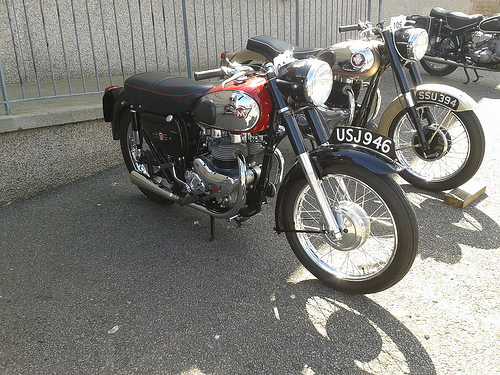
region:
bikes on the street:
[76, 22, 455, 272]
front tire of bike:
[270, 164, 405, 303]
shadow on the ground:
[247, 286, 353, 351]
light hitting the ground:
[418, 270, 477, 335]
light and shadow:
[347, 284, 452, 361]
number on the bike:
[321, 121, 395, 170]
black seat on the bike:
[139, 51, 195, 121]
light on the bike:
[291, 60, 342, 99]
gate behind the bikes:
[14, 16, 146, 77]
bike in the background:
[413, 7, 492, 64]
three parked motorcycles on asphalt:
[90, 10, 485, 308]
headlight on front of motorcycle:
[297, 57, 337, 109]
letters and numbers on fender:
[412, 86, 463, 109]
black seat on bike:
[120, 66, 206, 116]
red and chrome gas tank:
[202, 74, 272, 133]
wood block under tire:
[440, 179, 488, 214]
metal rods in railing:
[25, 19, 103, 88]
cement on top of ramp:
[24, 77, 104, 130]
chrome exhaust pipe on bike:
[122, 165, 190, 214]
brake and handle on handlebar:
[190, 62, 250, 92]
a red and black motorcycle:
[96, 23, 422, 305]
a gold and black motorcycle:
[237, 22, 488, 160]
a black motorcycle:
[397, 5, 498, 79]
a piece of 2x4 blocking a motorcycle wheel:
[436, 175, 488, 215]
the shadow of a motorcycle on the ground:
[199, 287, 442, 373]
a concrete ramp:
[3, 76, 162, 177]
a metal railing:
[1, 0, 383, 103]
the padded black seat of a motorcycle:
[122, 62, 212, 119]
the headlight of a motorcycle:
[302, 58, 341, 110]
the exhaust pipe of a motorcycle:
[123, 166, 183, 204]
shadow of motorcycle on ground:
[174, 250, 432, 374]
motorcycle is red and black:
[96, 25, 319, 206]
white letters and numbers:
[333, 116, 405, 160]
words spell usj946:
[319, 118, 394, 163]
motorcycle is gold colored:
[240, 21, 493, 184]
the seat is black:
[236, 30, 332, 60]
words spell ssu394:
[407, 77, 467, 119]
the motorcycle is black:
[401, 2, 498, 82]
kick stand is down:
[190, 195, 240, 252]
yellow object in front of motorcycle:
[431, 163, 493, 218]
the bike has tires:
[81, 74, 414, 282]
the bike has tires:
[110, 125, 355, 371]